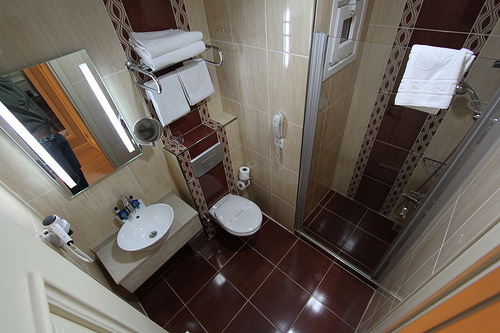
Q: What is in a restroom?
A: A mirror.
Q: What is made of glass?
A: A mirror.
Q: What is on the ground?
A: Tile.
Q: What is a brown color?
A: The tile.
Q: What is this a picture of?
A: A bathroom.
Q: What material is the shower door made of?
A: Glass.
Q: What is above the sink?
A: A mirror.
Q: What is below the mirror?
A: A sink.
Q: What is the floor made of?
A: Brown tile.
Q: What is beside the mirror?
A: A towel rack.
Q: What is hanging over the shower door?
A: A towel.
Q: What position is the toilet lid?
A: Down.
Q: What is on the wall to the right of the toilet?
A: A phone.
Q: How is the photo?
A: Clear.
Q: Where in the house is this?
A: Bathroom.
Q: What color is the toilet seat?
A: White.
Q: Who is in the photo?
A: Nobody.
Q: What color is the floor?
A: Brown.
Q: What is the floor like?
A: Tiled.